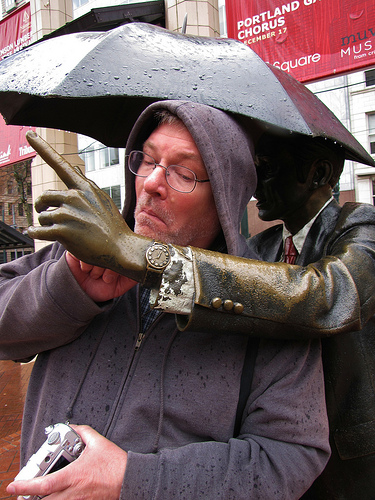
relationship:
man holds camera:
[13, 91, 328, 497] [1, 432, 80, 498]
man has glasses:
[13, 91, 328, 497] [125, 153, 235, 186]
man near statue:
[13, 91, 328, 497] [19, 110, 373, 410]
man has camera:
[13, 91, 328, 497] [1, 432, 80, 498]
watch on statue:
[135, 226, 190, 283] [19, 110, 373, 410]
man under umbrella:
[13, 91, 328, 497] [28, 12, 358, 193]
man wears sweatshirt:
[13, 91, 328, 497] [38, 241, 336, 497]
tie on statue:
[274, 223, 324, 273] [19, 110, 373, 410]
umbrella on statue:
[28, 12, 358, 193] [19, 110, 373, 410]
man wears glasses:
[13, 91, 328, 497] [125, 153, 235, 186]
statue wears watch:
[19, 110, 373, 410] [135, 226, 190, 283]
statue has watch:
[19, 110, 373, 410] [135, 226, 190, 283]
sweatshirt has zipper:
[38, 241, 336, 497] [119, 322, 154, 363]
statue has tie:
[19, 110, 373, 410] [274, 223, 324, 273]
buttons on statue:
[209, 291, 242, 312] [19, 110, 373, 410]